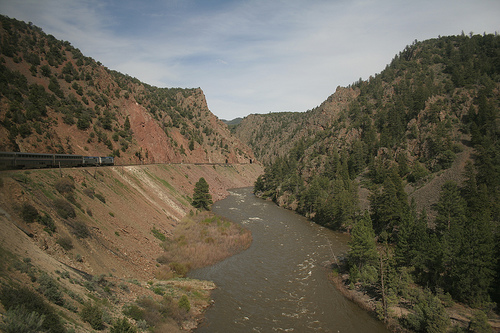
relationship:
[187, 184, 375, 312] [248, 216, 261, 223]
water has waves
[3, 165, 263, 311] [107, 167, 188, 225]
bank has a white spot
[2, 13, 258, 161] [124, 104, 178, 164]
mountain has a clear spot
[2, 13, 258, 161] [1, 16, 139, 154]
mountain has trees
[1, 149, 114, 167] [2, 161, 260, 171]
train on tracks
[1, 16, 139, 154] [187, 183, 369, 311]
trees are beside river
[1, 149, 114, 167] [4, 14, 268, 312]
train on side of a canyon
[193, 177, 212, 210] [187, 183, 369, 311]
tree by river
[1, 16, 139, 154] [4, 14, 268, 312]
trees are on right of canyon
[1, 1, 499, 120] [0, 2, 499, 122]
sky has clouds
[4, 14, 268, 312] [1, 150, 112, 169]
canyon next to a railroad